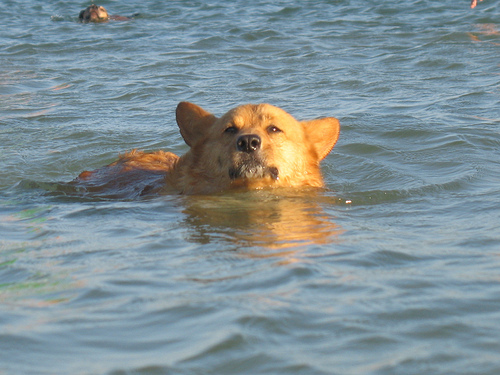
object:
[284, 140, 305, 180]
fur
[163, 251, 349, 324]
ripples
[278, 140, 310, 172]
light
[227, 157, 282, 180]
mouth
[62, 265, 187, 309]
ripples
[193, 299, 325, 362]
ripples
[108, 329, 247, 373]
ripples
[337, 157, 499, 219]
ripples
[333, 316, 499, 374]
ripples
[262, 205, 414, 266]
ripples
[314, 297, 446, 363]
ripples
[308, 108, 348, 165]
ears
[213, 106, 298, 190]
face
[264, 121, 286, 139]
eyes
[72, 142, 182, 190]
back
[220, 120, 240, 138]
eye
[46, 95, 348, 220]
dog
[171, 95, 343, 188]
head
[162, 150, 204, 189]
fur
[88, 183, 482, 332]
surface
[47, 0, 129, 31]
dog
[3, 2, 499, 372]
water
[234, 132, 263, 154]
black nose